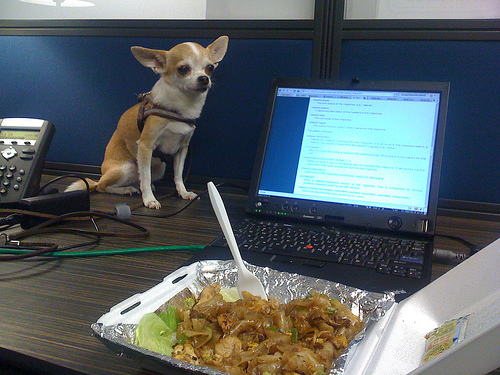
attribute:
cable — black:
[198, 186, 475, 264]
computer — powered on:
[181, 77, 453, 302]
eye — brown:
[175, 63, 193, 77]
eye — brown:
[201, 63, 216, 75]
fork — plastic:
[206, 185, 283, 299]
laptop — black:
[217, 73, 468, 296]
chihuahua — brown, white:
[64, 33, 230, 210]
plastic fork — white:
[202, 180, 269, 301]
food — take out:
[138, 282, 363, 372]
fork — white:
[204, 179, 274, 304]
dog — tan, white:
[95, 28, 240, 226]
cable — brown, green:
[64, 240, 85, 268]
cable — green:
[0, 235, 210, 256]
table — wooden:
[35, 174, 256, 328]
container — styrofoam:
[93, 227, 485, 371]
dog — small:
[92, 34, 238, 211]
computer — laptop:
[198, 67, 454, 287]